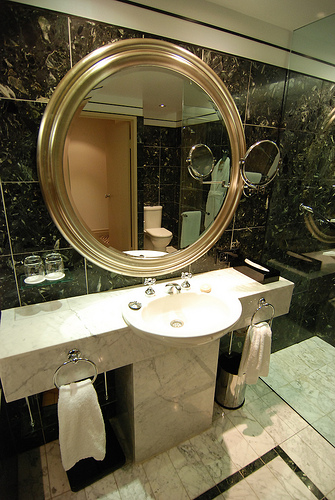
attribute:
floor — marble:
[4, 334, 333, 498]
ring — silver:
[39, 335, 112, 393]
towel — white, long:
[54, 376, 108, 468]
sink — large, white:
[120, 277, 242, 346]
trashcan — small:
[216, 353, 247, 410]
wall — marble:
[223, 37, 266, 95]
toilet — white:
[139, 184, 171, 252]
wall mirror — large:
[21, 33, 253, 274]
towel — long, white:
[231, 317, 272, 390]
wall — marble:
[0, 1, 285, 297]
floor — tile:
[247, 387, 308, 441]